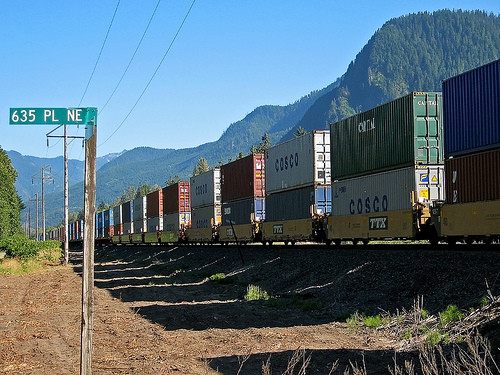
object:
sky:
[0, 0, 500, 159]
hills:
[275, 8, 500, 146]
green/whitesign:
[11, 107, 98, 125]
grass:
[435, 301, 467, 327]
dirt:
[0, 250, 500, 374]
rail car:
[327, 91, 418, 182]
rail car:
[331, 167, 414, 215]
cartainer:
[185, 164, 221, 241]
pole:
[79, 124, 101, 375]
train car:
[433, 56, 500, 245]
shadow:
[92, 245, 281, 297]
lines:
[78, 1, 123, 109]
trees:
[192, 153, 210, 178]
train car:
[259, 127, 331, 243]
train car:
[131, 193, 149, 245]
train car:
[120, 200, 133, 245]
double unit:
[161, 181, 193, 232]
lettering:
[41, 109, 50, 123]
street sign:
[7, 105, 98, 126]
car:
[184, 167, 222, 245]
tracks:
[93, 240, 500, 252]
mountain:
[275, 8, 500, 149]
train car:
[217, 153, 266, 246]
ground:
[0, 239, 500, 374]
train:
[38, 58, 500, 247]